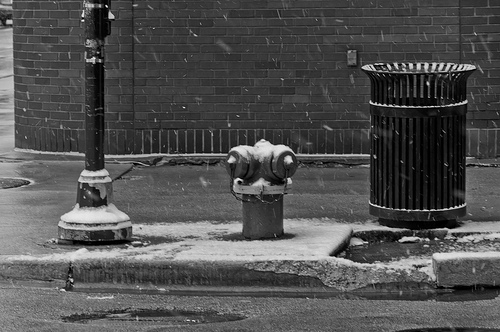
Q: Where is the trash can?
A: Sidewalk.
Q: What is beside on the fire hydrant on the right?
A: Pole.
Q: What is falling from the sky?
A: Snow.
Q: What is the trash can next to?
A: Fire hydrant.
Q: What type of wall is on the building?
A: Brick.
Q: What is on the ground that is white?
A: Snow.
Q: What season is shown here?
A: Winter.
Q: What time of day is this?
A: Afternoon.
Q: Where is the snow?
A: Ground.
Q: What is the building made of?
A: Brick.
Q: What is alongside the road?
A: Curb.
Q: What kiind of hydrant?
A: Fire.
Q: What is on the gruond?
A: Snow.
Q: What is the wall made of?
A: Brick.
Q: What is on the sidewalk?
A: A trash can.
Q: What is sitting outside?
A: A trash can.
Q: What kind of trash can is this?
A: A metal trash can.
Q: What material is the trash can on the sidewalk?
A: Metal.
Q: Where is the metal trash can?
A: On the sidewalk.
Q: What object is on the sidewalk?
A: A fire hydrant.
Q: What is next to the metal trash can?
A: A fire hyndrant.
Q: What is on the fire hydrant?
A: Snow.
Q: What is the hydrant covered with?
A: Snow.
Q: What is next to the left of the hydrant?
A: A street pole.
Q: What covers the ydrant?
A: Snow.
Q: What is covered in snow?
A: Streetlight.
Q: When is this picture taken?
A: In winter.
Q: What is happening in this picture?
A: It's snowing.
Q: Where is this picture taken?
A: Outside on a street.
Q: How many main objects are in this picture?
A: Three.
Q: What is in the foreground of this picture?
A: A post, a fire hydrant and a trash can.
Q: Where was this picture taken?
A: In an urban area.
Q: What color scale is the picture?
A: Black and white.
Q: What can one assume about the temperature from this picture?
A: That it's cold.